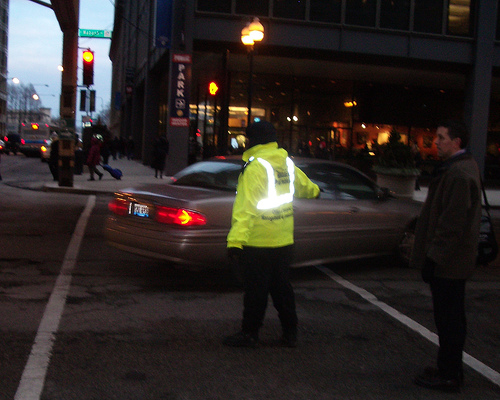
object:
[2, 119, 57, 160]
traffic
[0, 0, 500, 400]
city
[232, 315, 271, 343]
foot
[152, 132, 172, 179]
person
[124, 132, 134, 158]
person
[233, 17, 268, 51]
light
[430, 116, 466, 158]
head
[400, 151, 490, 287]
coat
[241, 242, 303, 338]
pant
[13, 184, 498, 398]
crosswalk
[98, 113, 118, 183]
people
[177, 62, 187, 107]
word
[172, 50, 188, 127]
sign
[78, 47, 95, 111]
traffic light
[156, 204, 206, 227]
light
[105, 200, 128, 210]
light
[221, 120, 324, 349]
man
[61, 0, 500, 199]
business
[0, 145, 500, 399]
street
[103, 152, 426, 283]
car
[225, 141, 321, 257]
coat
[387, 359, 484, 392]
curb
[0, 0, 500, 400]
area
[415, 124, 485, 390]
pedestrian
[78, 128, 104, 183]
pedestrians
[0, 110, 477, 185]
background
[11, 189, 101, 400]
line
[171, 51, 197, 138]
pole